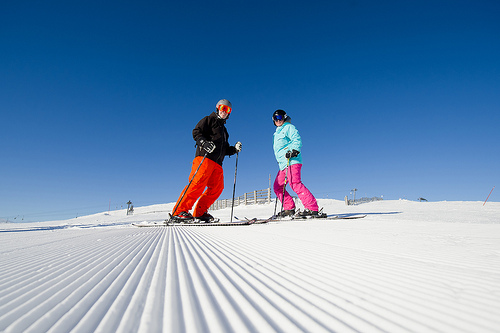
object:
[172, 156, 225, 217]
pants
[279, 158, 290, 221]
ski pole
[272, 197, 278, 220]
ski pole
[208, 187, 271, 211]
fence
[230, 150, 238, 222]
ski pole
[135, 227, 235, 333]
lines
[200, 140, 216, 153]
hand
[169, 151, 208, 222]
ski pole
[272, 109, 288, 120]
helmet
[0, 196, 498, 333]
ground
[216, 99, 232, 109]
helmet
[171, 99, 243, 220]
man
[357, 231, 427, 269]
white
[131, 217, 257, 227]
skis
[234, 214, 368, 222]
skis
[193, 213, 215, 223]
feet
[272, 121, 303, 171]
blue jacket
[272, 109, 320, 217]
female skier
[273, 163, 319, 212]
pants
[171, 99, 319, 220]
two people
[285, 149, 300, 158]
gloves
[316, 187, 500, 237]
groves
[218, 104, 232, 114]
goggles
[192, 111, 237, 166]
black jacket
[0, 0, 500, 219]
sky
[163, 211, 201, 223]
equipment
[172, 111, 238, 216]
clothing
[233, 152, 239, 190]
pole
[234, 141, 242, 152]
hand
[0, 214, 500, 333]
snow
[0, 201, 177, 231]
slope